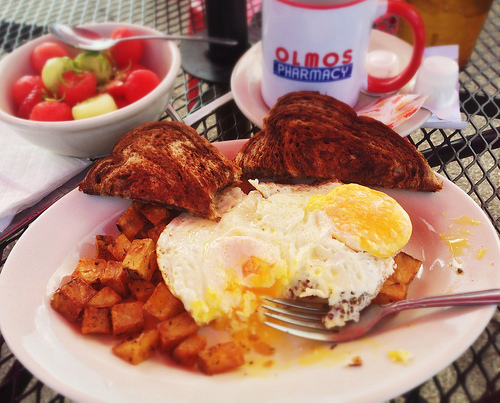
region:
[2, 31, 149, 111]
a fresh breakfast salad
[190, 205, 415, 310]
eggs sunny side up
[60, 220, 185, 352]
well seasoned breakfast potatoes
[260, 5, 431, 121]
a warm beverage and sweetener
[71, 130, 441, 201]
very crispy special toast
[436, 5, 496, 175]
an outdoor table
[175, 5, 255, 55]
a pink colored chair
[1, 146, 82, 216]
a quilted napkin weighed down by a bowl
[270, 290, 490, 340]
a fork on the right of the plate indicating is a right handed consumer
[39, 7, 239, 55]
a spoon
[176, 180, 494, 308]
Two eggs on the plate.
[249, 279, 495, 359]
Fork on the white plate.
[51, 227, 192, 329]
Home fries on the white plate.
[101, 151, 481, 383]
Breakfast on the table.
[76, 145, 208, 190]
Toast for breakfast.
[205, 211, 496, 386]
Eggs with the fork.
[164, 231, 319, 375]
Dippy eggs on the plate.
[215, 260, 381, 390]
White plate on the table.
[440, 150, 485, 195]
Outdoor table.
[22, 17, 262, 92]
Spoon on the bowl.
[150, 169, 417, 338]
over medium eggs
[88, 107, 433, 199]
two pieces of brown toast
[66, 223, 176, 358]
medium diced breakfast potatoes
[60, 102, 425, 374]
a typical american breakfast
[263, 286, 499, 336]
a small silver fork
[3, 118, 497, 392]
a simple white plate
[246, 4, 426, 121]
a red and white coffee cup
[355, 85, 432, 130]
red and white sugar packets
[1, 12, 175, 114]
a bowl of cherry tomatoes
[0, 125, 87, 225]
a white paper napkin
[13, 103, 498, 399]
white plate with food on it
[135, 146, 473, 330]
two fried eggs on plate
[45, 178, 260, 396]
potato squares on plate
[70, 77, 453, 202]
two slices of brown bread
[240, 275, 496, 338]
silver fork on plate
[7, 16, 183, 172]
bowl of fruit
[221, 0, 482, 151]
cup of teal on saucer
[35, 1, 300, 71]
silver spoon in bowl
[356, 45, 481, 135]
satchets of sugar and milk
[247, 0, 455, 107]
white and red cup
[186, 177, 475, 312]
Two dippy eggs.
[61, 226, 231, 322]
Hash browns on the plate.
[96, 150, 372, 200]
Toast on the plate for breakfast.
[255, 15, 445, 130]
Coffee mug on saucer.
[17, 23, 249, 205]
Mini tomatoes in a side dish.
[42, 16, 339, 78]
Spoon in the tomato dish.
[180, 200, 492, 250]
Two eggs on the plate.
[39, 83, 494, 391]
Breakfast served on a plate.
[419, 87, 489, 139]
Lunch on an outdoor table.